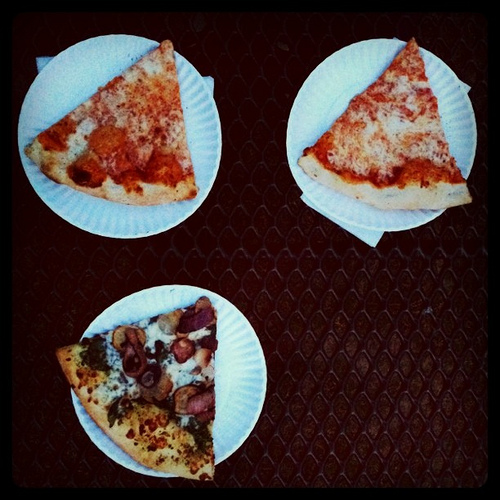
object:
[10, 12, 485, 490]
table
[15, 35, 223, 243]
plate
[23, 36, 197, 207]
pizza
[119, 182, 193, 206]
crust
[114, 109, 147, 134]
cheese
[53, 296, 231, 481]
pizza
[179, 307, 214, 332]
onion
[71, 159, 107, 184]
burn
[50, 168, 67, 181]
bubble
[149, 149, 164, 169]
sauce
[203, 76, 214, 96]
napkin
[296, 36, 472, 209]
pizza